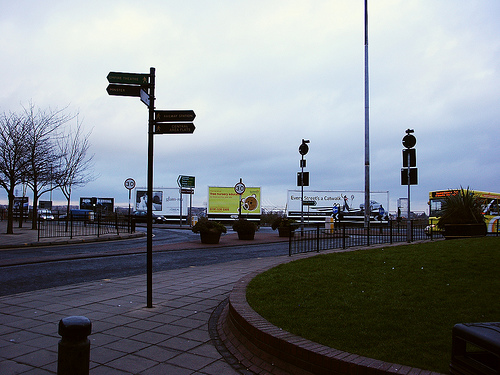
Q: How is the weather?
A: Overcast.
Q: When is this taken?
A: Daytime.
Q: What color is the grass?
A: Green.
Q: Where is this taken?
A: A city street.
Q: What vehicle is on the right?
A: A bus.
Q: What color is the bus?
A: Yellow.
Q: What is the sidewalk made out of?
A: Tiles.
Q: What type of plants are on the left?
A: Trees.